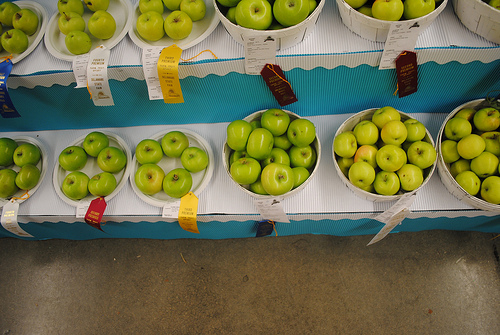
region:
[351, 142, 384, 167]
a green an red apple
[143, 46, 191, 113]
yellow and white tags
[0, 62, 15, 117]
a blue tag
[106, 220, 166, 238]
a light blue table cloth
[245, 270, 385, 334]
the brown ground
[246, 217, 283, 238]
a black an yellow tag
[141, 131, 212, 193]
5 apples on a plate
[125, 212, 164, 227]
white railing on the table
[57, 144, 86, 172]
green apple on display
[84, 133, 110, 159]
green apple on display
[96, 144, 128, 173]
green apple on display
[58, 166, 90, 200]
green apple on display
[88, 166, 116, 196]
green apple on display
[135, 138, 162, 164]
green apple on display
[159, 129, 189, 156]
green apple on display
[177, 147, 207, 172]
green apple on display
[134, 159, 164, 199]
green apple on display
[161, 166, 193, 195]
green apple on display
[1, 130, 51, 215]
The apples are on a plate.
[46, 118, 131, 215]
The apples are on a plate.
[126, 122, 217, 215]
The apples are on a plate.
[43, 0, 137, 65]
The apples are on a plate.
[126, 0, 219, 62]
The apples are on a plate.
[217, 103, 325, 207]
The apples are in a basket.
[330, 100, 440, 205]
The apples are in a basket.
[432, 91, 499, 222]
The apples are in a basket.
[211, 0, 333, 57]
The apples are in a basket.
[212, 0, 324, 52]
green apples in a white bowl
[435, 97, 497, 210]
green apples in a white bowl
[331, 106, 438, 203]
green apples in a white bowl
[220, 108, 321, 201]
green apples in a white bowl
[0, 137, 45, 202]
green apples on a white plate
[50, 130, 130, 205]
green apples on a white plate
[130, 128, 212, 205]
green apples on a white plate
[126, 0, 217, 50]
green apples on a white plate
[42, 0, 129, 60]
green apples on a white plate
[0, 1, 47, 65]
green apples on a white plate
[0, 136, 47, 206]
green apples on a white plate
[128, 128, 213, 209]
green apples on a white plate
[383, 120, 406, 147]
green apple in bucket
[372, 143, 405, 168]
green apple in bucket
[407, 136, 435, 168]
green apple in bucket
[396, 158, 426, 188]
green apple in bucket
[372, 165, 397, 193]
green apple in bucket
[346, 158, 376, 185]
green apple in bucket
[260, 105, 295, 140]
green apple in bucket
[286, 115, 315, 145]
green apple in bucket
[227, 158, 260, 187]
green apple in bucket